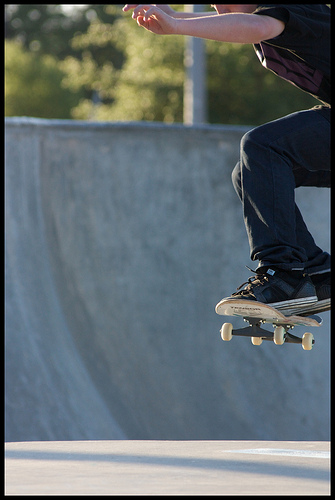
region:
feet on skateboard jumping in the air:
[169, 236, 328, 396]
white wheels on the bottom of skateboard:
[213, 319, 289, 354]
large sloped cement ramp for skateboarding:
[16, 87, 262, 373]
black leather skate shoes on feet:
[200, 249, 331, 356]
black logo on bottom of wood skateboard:
[232, 301, 264, 321]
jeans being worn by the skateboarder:
[207, 96, 329, 301]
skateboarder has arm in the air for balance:
[116, 1, 317, 71]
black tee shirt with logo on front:
[241, 5, 332, 110]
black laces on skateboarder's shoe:
[222, 259, 273, 297]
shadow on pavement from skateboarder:
[56, 420, 306, 486]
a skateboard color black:
[206, 292, 328, 358]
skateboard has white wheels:
[213, 318, 319, 357]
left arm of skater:
[121, 4, 297, 48]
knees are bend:
[216, 116, 307, 204]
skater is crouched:
[115, 6, 328, 317]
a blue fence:
[14, 108, 324, 440]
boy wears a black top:
[116, 0, 329, 138]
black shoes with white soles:
[208, 250, 328, 318]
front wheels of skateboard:
[217, 318, 287, 344]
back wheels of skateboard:
[249, 334, 316, 350]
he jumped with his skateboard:
[112, 3, 334, 374]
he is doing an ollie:
[111, 2, 333, 390]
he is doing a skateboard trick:
[118, 5, 333, 394]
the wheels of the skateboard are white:
[211, 323, 325, 351]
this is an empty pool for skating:
[8, 117, 331, 492]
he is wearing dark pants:
[215, 95, 334, 303]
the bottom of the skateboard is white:
[196, 293, 330, 352]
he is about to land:
[107, 5, 332, 391]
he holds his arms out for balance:
[101, 2, 333, 496]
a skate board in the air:
[210, 298, 325, 346]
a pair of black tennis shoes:
[228, 259, 332, 310]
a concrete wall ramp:
[6, 124, 225, 434]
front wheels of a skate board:
[217, 320, 287, 342]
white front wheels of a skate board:
[218, 323, 294, 344]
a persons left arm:
[121, 4, 294, 44]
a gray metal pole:
[177, 41, 221, 125]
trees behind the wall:
[8, 9, 177, 114]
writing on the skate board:
[228, 304, 265, 312]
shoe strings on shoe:
[236, 263, 262, 289]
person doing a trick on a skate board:
[213, 185, 324, 363]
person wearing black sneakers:
[218, 252, 330, 317]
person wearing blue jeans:
[221, 94, 332, 289]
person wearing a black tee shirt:
[251, 2, 326, 80]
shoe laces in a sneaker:
[230, 269, 264, 295]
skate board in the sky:
[199, 219, 328, 357]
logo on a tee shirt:
[249, 38, 328, 93]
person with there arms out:
[139, 8, 278, 55]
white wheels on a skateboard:
[217, 321, 288, 346]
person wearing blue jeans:
[221, 99, 319, 256]